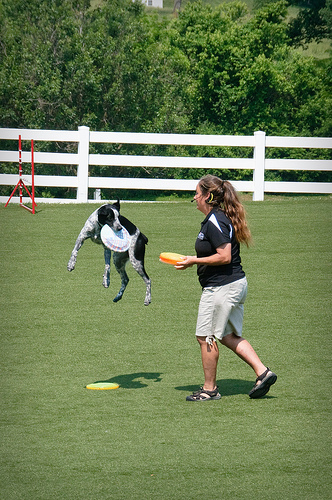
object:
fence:
[0, 123, 331, 206]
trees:
[129, 37, 199, 195]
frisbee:
[159, 251, 194, 268]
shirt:
[194, 205, 247, 293]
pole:
[29, 138, 35, 212]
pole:
[17, 134, 23, 205]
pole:
[20, 203, 35, 213]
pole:
[3, 180, 19, 207]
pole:
[20, 179, 37, 206]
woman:
[173, 173, 279, 403]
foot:
[187, 385, 220, 400]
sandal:
[185, 385, 223, 402]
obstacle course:
[3, 134, 39, 213]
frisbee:
[85, 381, 120, 391]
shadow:
[83, 371, 165, 389]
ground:
[0, 193, 332, 500]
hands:
[173, 255, 195, 271]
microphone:
[190, 192, 213, 203]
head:
[193, 173, 222, 215]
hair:
[197, 173, 257, 251]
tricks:
[67, 172, 275, 420]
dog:
[66, 196, 152, 307]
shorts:
[194, 276, 248, 348]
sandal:
[248, 367, 277, 400]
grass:
[0, 197, 332, 500]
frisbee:
[100, 221, 132, 254]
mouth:
[107, 222, 124, 232]